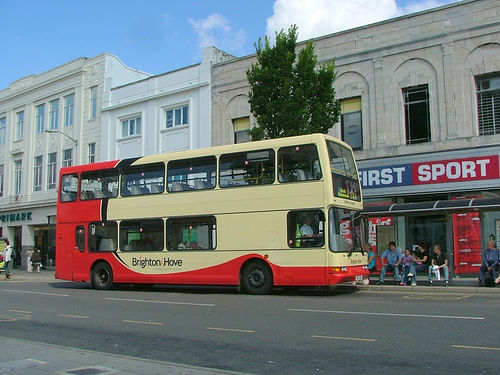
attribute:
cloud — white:
[188, 12, 249, 62]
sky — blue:
[2, 1, 462, 90]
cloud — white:
[262, 0, 402, 46]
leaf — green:
[264, 89, 294, 109]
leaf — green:
[273, 77, 313, 107]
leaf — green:
[275, 75, 326, 109]